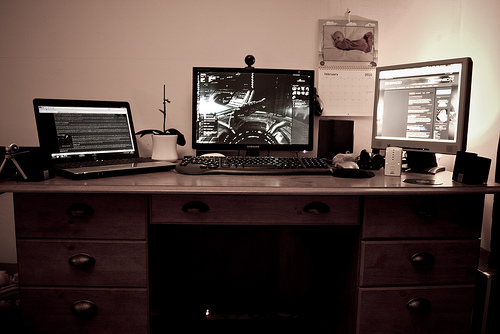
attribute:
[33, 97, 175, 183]
laptop — opened, black, grey, open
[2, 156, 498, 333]
desk — large, wooden, wood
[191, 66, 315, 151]
monitor — black, on, flat screen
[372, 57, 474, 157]
monitor — grey, on, flat screen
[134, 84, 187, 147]
plant — small, dead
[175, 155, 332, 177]
keyboard — black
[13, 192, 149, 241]
drawer — wood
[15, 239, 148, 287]
drawer — wood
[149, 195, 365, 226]
drawer — middle, closed, wood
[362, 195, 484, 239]
drawer — wood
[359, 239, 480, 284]
drawer — wood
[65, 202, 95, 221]
handle — brass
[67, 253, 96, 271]
handle — brass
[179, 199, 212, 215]
handle — brass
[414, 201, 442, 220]
handle — brass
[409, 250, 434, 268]
handle — brass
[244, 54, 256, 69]
webcam — black, small, round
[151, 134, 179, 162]
pot — small, white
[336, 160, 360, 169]
computer mouse — grey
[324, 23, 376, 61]
picture — of baby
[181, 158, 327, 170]
buttons — black